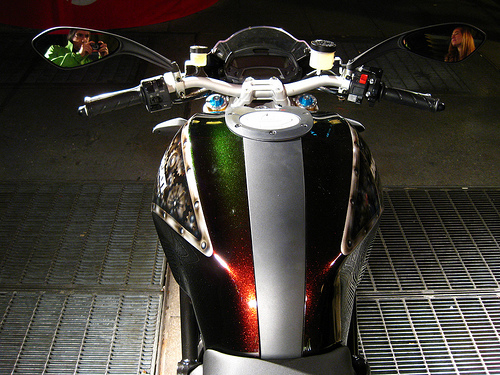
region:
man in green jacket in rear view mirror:
[40, 28, 114, 65]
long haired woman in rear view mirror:
[400, 27, 483, 65]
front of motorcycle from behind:
[25, 18, 487, 365]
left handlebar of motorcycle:
[61, 75, 243, 116]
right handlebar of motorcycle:
[292, 65, 446, 117]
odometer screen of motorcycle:
[223, 58, 307, 78]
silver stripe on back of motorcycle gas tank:
[230, 134, 323, 364]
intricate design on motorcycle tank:
[152, 123, 216, 265]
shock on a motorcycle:
[174, 285, 203, 372]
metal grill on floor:
[27, 187, 154, 292]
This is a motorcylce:
[83, 24, 474, 328]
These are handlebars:
[50, 39, 462, 127]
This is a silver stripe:
[251, 132, 303, 349]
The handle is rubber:
[91, 67, 176, 179]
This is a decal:
[143, 174, 235, 280]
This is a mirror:
[23, 3, 115, 103]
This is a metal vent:
[45, 231, 96, 337]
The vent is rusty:
[48, 259, 98, 374]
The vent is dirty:
[16, 250, 133, 357]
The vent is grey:
[126, 319, 143, 370]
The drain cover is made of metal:
[29, 209, 115, 359]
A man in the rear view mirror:
[27, 8, 149, 82]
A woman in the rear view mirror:
[394, 11, 487, 76]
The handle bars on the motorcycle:
[70, 60, 448, 132]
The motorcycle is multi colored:
[136, 122, 408, 363]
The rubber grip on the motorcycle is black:
[381, 75, 444, 123]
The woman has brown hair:
[428, 21, 475, 68]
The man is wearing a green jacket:
[43, 28, 116, 71]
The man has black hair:
[59, 23, 98, 53]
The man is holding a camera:
[47, 28, 112, 61]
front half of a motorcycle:
[7, 10, 488, 366]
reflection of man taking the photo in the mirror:
[30, 25, 110, 70]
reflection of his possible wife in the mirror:
[405, 17, 480, 67]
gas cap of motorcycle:
[220, 102, 314, 142]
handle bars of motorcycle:
[59, 74, 444, 111]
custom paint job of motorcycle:
[152, 113, 389, 354]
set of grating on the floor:
[0, 181, 167, 370]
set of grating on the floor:
[353, 173, 498, 373]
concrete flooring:
[354, 90, 497, 185]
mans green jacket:
[44, 45, 88, 69]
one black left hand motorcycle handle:
[66, 71, 171, 120]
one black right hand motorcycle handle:
[347, 68, 449, 117]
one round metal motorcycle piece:
[220, 94, 313, 141]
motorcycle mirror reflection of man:
[23, 22, 118, 72]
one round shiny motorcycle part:
[201, 89, 230, 111]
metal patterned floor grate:
[363, 294, 499, 364]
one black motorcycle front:
[19, 22, 481, 368]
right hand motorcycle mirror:
[371, 20, 489, 66]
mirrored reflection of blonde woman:
[435, 22, 484, 62]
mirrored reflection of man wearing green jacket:
[33, 19, 115, 68]